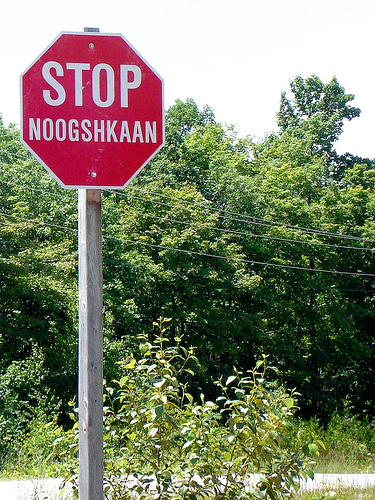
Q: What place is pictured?
A: It is a forest.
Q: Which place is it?
A: It is a forest.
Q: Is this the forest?
A: Yes, it is the forest.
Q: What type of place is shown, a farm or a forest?
A: It is a forest.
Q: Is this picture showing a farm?
A: No, the picture is showing a forest.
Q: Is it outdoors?
A: Yes, it is outdoors.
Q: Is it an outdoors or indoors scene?
A: It is outdoors.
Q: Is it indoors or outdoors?
A: It is outdoors.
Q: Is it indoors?
A: No, it is outdoors.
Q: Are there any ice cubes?
A: No, there are no ice cubes.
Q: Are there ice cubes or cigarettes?
A: No, there are no ice cubes or cigarettes.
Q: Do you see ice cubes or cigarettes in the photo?
A: No, there are no ice cubes or cigarettes.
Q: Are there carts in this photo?
A: No, there are no carts.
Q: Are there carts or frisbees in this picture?
A: No, there are no carts or frisbees.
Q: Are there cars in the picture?
A: No, there are no cars.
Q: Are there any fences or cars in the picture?
A: No, there are no cars or fences.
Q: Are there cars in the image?
A: No, there are no cars.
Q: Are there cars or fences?
A: No, there are no cars or fences.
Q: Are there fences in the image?
A: No, there are no fences.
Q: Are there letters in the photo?
A: Yes, there are letters.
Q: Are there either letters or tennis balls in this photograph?
A: Yes, there are letters.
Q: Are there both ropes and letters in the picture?
A: No, there are letters but no ropes.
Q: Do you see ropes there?
A: No, there are no ropes.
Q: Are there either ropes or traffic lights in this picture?
A: No, there are no ropes or traffic lights.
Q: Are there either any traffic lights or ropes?
A: No, there are no ropes or traffic lights.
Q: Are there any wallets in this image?
A: No, there are no wallets.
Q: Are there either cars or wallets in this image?
A: No, there are no wallets or cars.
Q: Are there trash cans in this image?
A: No, there are no trash cans.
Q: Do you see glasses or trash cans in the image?
A: No, there are no trash cans or glasses.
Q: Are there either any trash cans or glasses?
A: No, there are no trash cans or glasses.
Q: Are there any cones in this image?
A: No, there are no cones.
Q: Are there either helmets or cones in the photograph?
A: No, there are no cones or helmets.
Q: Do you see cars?
A: No, there are no cars.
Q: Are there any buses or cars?
A: No, there are no cars or buses.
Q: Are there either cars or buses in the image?
A: No, there are no cars or buses.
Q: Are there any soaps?
A: No, there are no soaps.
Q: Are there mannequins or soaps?
A: No, there are no soaps or mannequins.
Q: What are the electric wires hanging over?
A: The wires are hanging over the road.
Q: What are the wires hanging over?
A: The wires are hanging over the road.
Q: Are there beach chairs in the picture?
A: No, there are no beach chairs.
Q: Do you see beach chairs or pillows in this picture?
A: No, there are no beach chairs or pillows.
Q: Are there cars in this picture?
A: No, there are no cars.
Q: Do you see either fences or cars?
A: No, there are no cars or fences.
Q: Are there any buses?
A: No, there are no buses.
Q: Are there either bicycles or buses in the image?
A: No, there are no buses or bicycles.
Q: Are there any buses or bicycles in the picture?
A: No, there are no buses or bicycles.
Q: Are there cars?
A: No, there are no cars.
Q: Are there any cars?
A: No, there are no cars.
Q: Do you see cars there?
A: No, there are no cars.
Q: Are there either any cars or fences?
A: No, there are no cars or fences.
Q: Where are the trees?
A: The trees are in the forest.